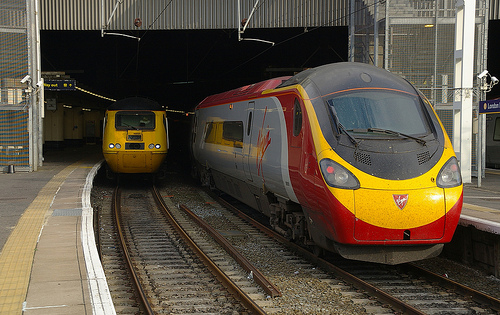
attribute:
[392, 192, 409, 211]
logo — red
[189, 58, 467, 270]
train — virgin, ready to move, red, yellow, gray red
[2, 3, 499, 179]
train station — nice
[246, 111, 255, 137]
window — circular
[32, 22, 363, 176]
entrance — tunnelled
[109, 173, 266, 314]
train tracks — brown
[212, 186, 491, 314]
train tracks — brown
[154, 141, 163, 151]
light — on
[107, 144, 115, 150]
light — on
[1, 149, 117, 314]
cement — gray, brown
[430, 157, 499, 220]
cement — gray, brown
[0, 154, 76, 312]
curbing — yellow, tiled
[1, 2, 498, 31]
sheeting — corrugated metal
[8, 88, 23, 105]
window — lit